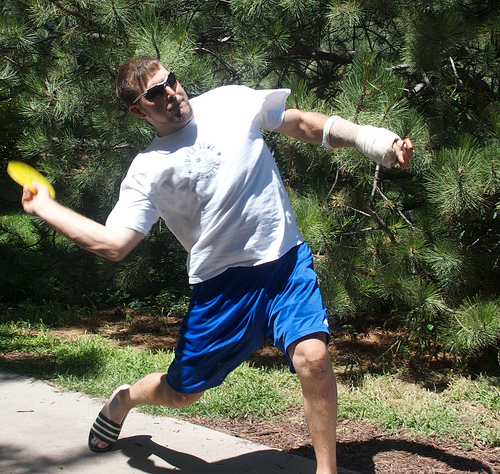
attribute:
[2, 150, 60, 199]
frisbee — round, yellow, disc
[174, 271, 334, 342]
shorts — blue, loose, comfy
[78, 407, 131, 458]
sandals — blue, flipflop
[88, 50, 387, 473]
man — throwing, playing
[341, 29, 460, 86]
tree — pine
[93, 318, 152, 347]
trail — dirt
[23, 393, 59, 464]
path — concrete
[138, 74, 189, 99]
sunglasses — black, dark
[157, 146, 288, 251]
tshirt — white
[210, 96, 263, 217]
shirt — tee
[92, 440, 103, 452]
shoe — black, white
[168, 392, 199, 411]
knee — bent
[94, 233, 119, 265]
skin — pale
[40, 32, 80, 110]
trees — growing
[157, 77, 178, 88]
glasses — sun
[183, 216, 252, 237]
shirt — white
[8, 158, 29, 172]
frisbee — yellow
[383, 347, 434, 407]
trail — path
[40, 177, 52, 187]
frisbee — yellow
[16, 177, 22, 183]
frisbee — round